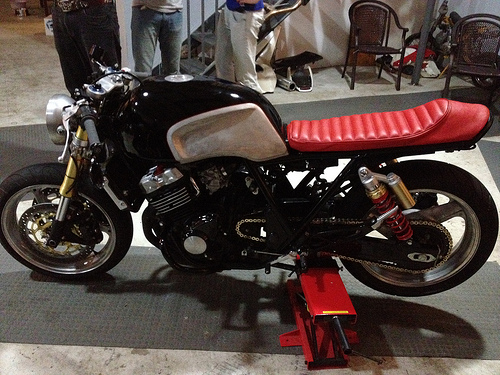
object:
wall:
[287, 16, 340, 45]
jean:
[129, 7, 183, 77]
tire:
[334, 159, 499, 298]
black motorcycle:
[0, 45, 499, 297]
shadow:
[23, 261, 484, 375]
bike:
[0, 46, 497, 297]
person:
[215, 0, 276, 92]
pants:
[214, 10, 265, 94]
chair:
[339, 0, 408, 91]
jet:
[0, 45, 500, 299]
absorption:
[356, 166, 415, 242]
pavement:
[0, 158, 500, 375]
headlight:
[46, 94, 76, 146]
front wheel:
[0, 162, 132, 280]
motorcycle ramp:
[279, 250, 358, 371]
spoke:
[403, 208, 421, 215]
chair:
[442, 13, 500, 96]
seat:
[282, 98, 489, 153]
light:
[45, 93, 76, 145]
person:
[131, 0, 186, 82]